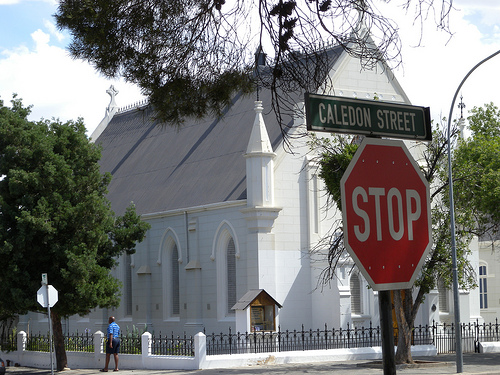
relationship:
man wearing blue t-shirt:
[99, 314, 118, 374] [107, 322, 122, 339]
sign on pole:
[341, 141, 433, 291] [378, 288, 400, 374]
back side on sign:
[34, 283, 57, 305] [36, 286, 58, 308]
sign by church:
[341, 141, 433, 291] [54, 17, 447, 342]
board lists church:
[237, 283, 287, 334] [131, 133, 306, 300]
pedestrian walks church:
[97, 314, 127, 365] [54, 17, 447, 342]